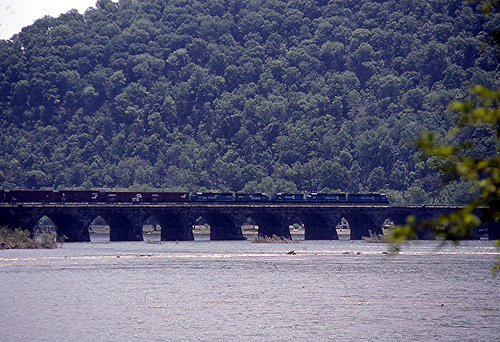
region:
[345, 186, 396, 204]
train car on the tracks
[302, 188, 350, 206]
train car on the tracks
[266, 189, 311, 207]
train car on the tracks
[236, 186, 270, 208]
train car on the tracks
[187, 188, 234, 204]
train car on the tracks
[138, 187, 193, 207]
train car on the tracks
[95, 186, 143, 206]
train car on the tracks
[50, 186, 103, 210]
train car on the tracks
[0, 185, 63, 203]
train car on the tracks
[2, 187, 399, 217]
train on the tracks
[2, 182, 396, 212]
a train crossing the bridge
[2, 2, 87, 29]
a corner of the sky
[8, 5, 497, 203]
a hill covered up in trees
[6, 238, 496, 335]
the water next to the bridge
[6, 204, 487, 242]
the bridge above the water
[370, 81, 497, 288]
green leaves attached to the branches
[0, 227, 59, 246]
the grass next to the bridge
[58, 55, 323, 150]
some trees on the hill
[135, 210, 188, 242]
an arch on the bridge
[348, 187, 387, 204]
the front of the train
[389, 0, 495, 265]
greenish-yellow leaves on right side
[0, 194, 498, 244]
bridge with multiple arches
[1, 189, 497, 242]
dark gray stone bridge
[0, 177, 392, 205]
blue train with red cargo cars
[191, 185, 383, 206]
blue train cars with white letters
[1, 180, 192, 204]
reddish brown cargo cars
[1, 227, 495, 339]
gray water under the bridge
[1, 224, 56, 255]
small bushes left side of bridge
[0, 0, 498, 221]
lush green trees in background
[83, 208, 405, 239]
partial view of sandy shoreline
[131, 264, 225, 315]
a wide sea water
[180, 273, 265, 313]
a wide sea water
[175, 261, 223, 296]
a wide sea water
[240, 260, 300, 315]
a wide sea water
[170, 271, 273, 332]
a wide sea water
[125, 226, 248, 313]
a wide sea water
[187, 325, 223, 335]
a wide sea water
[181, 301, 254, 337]
a wide sea water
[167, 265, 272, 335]
a wide sea water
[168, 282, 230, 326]
a wide sea water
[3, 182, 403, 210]
the train on the tracks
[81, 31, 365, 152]
lush green trees on the mountain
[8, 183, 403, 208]
the train on a bridge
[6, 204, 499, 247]
the bridge over the water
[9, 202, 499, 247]
the bridge is made of stone or brick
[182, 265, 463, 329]
the water is calm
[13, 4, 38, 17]
the sky is blue and clear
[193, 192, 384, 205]
the train is blue and brown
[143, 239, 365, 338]
the water is moving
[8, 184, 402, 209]
the train is moving